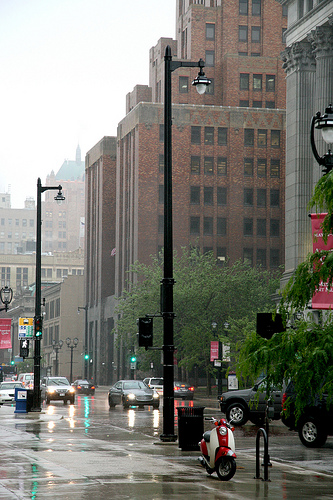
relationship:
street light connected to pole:
[159, 44, 211, 441] [189, 67, 211, 95]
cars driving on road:
[0, 373, 331, 447] [45, 389, 332, 482]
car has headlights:
[107, 379, 159, 410] [126, 393, 158, 401]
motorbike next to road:
[198, 413, 238, 481] [45, 389, 332, 482]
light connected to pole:
[33, 316, 43, 340] [31, 177, 45, 412]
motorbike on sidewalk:
[198, 413, 238, 481] [1, 404, 332, 499]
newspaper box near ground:
[14, 388, 28, 412] [1, 378, 333, 499]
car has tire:
[107, 379, 159, 410] [122, 397, 130, 407]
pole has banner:
[31, 177, 45, 412] [18, 319, 34, 337]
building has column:
[278, 1, 331, 327] [281, 44, 313, 288]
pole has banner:
[34, 177, 42, 411] [18, 319, 34, 337]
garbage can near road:
[176, 403, 203, 450] [45, 389, 332, 482]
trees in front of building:
[113, 163, 330, 426] [85, 1, 283, 386]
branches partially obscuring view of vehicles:
[228, 323, 332, 429] [206, 347, 321, 442]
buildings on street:
[0, 0, 331, 385] [32, 361, 305, 466]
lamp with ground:
[17, 158, 75, 428] [1, 378, 333, 499]